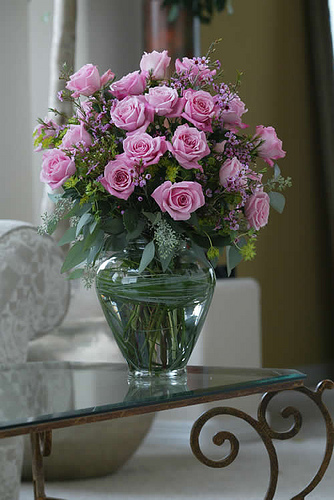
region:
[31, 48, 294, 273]
Pink roses in the vase.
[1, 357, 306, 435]
Glass table top on the frame.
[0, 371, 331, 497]
Metal framing under table top.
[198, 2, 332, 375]
Yellow wood wall in the background.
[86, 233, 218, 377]
Clear vase on the table.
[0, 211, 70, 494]
White floral design couch arm in the background.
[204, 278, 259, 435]
White half wall in the background.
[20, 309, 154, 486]
Large beige vase on the floor.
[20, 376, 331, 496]
White carpeting covering the floor.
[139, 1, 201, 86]
Brown wood column molding on the wall.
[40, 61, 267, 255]
purple flowers in vase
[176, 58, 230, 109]
purple buds on flowers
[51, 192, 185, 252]
white flowers in bunch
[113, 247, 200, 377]
vase is wide and round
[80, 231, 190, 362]
vase on clear table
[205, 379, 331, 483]
green legs on table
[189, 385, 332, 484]
table legs are round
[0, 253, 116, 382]
white sofa behind table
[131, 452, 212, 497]
white carpet under table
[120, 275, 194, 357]
green stems on flowers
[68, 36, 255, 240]
lavender flowers in vase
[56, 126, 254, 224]
green leaves with flowers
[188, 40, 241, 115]
purple buds on flowers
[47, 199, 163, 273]
green leaves below lavender flowers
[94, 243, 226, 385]
vase is wide and clear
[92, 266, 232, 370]
vase on clear table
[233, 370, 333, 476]
dark grey legs on table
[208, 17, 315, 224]
tan wall in background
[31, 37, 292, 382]
a vase of roses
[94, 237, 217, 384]
a clear glass vase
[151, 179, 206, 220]
one pink rose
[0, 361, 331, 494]
a glass topped coffee table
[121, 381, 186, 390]
a reflection in a glass tabletop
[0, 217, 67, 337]
the arm of a chair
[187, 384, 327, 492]
fancy scroll work of a table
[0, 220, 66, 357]
the gray and white pattern in the arm of a chair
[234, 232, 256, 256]
tiny yellow flowers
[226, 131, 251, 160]
a cluster of small purple flowers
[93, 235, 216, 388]
very large clear rose vase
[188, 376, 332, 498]
wrought iron curly Q's desigs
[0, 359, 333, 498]
wrought iron table with large glass top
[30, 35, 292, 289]
large pink, white, and green bouquet of roses and baby's breath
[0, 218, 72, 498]
white designer sofa with huge arm rests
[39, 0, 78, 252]
large trunk to an indoor palm tree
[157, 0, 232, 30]
some green and yellow leaves from the palm tree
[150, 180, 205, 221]
beautifly blossomes pink rose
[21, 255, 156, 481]
large ceramic vase ecru in color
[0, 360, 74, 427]
reflection of the sofa in the glass